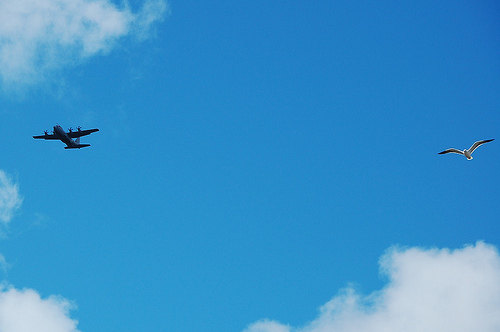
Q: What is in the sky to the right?
A: A bird.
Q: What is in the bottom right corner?
A: Cloud.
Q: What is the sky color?
A: Blue.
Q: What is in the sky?
A: Bird.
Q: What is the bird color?
A: White and black.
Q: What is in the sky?
A: An airplane.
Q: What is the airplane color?
A: Grey.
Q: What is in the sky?
A: Clouds.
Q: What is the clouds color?
A: White.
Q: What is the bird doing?
A: Flying.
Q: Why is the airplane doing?
A: Flying.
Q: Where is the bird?
A: Sky.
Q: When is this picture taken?
A: Daytime.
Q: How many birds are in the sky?
A: One.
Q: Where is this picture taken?
A: In the sky.